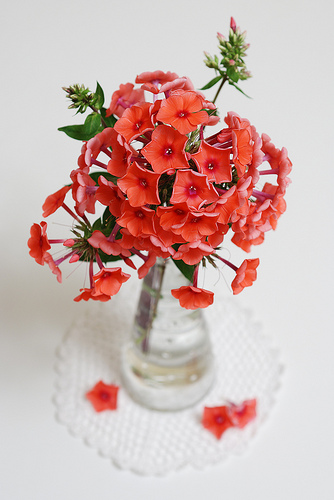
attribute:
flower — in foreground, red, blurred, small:
[88, 379, 120, 413]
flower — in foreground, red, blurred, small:
[199, 402, 237, 441]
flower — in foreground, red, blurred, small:
[227, 397, 261, 429]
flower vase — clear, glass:
[122, 255, 215, 408]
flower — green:
[200, 34, 255, 100]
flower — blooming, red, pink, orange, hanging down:
[168, 284, 215, 313]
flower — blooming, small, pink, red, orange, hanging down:
[229, 256, 261, 293]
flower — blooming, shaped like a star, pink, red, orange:
[166, 166, 211, 211]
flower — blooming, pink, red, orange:
[90, 267, 133, 299]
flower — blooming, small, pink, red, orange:
[27, 219, 53, 266]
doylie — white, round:
[56, 298, 283, 476]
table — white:
[3, 199, 332, 499]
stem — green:
[208, 79, 228, 104]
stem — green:
[138, 261, 166, 362]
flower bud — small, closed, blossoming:
[67, 92, 81, 101]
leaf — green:
[91, 82, 103, 111]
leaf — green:
[80, 112, 102, 137]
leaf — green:
[57, 125, 103, 141]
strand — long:
[212, 252, 237, 271]